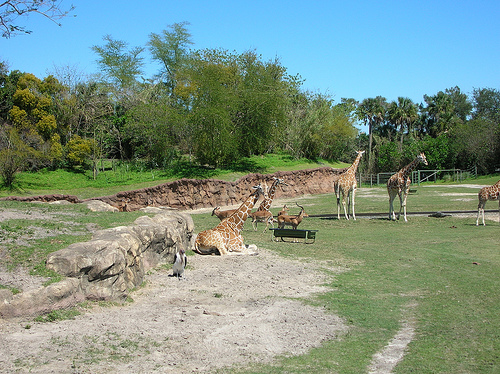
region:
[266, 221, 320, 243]
a black bench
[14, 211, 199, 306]
a group of rocks in field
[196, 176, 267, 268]
a giraffee laying down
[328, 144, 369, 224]
a giraffee standing up in the field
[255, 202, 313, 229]
small animals looking out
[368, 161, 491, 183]
a white fence out in the background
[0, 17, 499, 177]
a group of green trees in background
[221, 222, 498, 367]
a green grassy field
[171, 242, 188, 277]
a penguin in the sand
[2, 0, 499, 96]
blue skies above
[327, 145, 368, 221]
giraffe is in a park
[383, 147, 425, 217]
giraffe with neck bent forward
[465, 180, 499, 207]
giraffe walking out of shot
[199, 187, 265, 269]
giraffe lying next to stones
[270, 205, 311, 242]
gazelle feeding at a trough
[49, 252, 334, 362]
ground is very bare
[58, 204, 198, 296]
stone ledge near giraffe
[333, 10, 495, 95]
sky is a deep blue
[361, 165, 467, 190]
fence off in the distance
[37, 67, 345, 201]
trees overlooking park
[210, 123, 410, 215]
the giraffe is tall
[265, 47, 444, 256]
the giraffe is tall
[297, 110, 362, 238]
the giraffe is tall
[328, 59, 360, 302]
the giraffe is tall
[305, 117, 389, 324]
the giraffe is tall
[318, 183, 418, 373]
the giraffe is tall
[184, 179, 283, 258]
giraffe laying on the grown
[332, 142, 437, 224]
two baby giraffe standing on the grass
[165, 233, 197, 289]
bird standing on the grown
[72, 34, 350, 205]
forest green trees on a hill top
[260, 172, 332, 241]
2 different species of animals together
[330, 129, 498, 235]
giraffes in their natural habitat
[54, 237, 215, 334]
gray rocks and dirt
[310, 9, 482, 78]
bright clear blue sky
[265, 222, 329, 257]
animal feeding plastic bin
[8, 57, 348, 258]
forest in the background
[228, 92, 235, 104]
leaves of a tree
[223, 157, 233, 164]
stem of a tree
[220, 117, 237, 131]
leaves of a tree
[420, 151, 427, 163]
head of a giraffe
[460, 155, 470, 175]
part of a fence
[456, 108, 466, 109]
part of a forest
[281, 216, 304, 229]
part of a bench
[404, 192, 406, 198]
leg of a giraffe